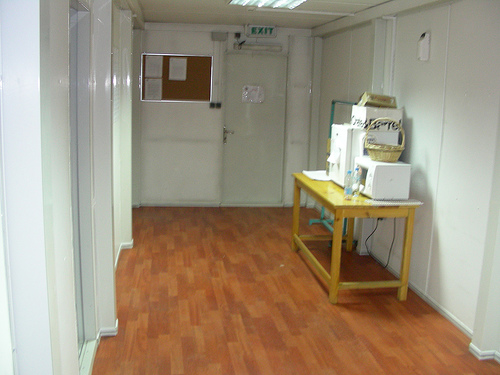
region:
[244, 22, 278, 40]
Exit sign above a door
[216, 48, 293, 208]
Light colored door with silver handle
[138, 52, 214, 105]
Bulletin board with papers attached to it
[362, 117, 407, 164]
A woven basket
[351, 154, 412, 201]
A white microwave sitting on a table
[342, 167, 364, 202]
A couple of water bottles with blue tops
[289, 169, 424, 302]
A wooden table with stuff on it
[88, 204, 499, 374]
Hardwood flooring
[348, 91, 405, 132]
A couple of boxes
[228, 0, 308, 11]
Fluorescent light on the ceiling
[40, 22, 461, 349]
a hallway in a building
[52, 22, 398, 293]
this hallway is almost empty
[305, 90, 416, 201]
stuff on the table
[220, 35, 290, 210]
a door to the hall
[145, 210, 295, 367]
wooden floors in a hall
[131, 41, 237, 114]
a bulletin board on the wall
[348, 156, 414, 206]
a microwave in the hall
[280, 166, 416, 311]
a table in the hall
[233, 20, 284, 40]
an exit sign on the wall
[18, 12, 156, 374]
other entrance points to the hall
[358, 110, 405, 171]
a basket over microwave oven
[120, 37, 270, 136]
cork board on the wall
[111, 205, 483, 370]
Floor made of wood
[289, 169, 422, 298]
Brown wooden table beside wall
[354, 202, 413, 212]
White microwave on table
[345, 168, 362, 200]
Two bottles on table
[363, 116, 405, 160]
Basket on top of microwave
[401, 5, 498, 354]
Wall painted in white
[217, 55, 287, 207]
Closed door beside window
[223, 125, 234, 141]
Silver handle on door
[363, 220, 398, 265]
Electrical cable on wall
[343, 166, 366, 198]
Bottles beside a microwave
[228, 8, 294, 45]
an exit sign above the door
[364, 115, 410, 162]
a basket sitting on a machine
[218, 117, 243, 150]
a door handle on the door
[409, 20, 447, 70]
paper hanging on the wall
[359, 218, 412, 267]
a power cord under the table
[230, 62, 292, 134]
a paper posted on the door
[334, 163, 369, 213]
a bottle sitting on a table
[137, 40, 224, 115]
a cork board hanging on the wall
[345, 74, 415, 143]
boxes on top of other items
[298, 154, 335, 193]
a paper laying on the table